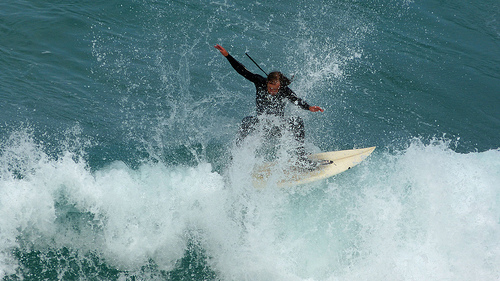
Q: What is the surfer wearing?
A: Wetsuit.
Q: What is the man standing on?
A: Surfboard.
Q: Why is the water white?
A: Wave.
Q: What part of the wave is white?
A: Crest.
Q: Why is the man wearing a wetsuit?
A: He's surfing.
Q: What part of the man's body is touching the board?
A: Feet.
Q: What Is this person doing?
A: Surfing.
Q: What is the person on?
A: A surfboard.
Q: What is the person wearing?
A: A wetsuit.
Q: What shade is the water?
A: Aqua green.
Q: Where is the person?
A: At the ocean.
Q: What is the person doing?
A: Surfing the waves.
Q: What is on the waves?
A: A person.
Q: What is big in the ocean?
A: The waves.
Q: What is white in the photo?
A: The foam.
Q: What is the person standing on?
A: A surfboard.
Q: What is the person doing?
A: Riding a wave.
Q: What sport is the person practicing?
A: Surfing.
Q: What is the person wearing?
A: A wetsuit.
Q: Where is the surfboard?
A: In the water.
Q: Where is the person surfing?
A: At the beach.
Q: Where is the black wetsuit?
A: On the person.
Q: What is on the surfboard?
A: A person.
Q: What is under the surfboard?
A: Water.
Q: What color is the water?
A: Blue.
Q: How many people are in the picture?
A: One.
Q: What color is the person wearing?
A: Black.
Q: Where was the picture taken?
A: In the ocean.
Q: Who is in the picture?
A: A surfer.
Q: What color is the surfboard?
A: White.